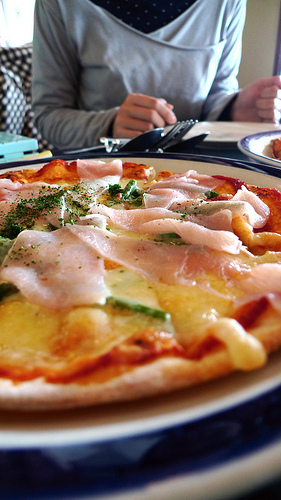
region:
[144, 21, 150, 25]
white dot on shirt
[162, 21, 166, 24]
white dot on shirt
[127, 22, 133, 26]
white dot on shirt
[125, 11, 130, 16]
white dot on shirt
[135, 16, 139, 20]
white dot on shirt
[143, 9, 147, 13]
white dot on shirt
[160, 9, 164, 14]
white dot on shirt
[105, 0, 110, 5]
white dot on shirt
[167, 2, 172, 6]
white dot on shirt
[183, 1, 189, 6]
white dot on shirt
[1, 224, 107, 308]
ham slices on the pizza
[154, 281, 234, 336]
pineapple chunks on the pizza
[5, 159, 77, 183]
brown toasted pizza crust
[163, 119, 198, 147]
a dinner fork on the table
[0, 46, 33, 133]
a black sofa with white polka dots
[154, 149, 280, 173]
a round pizza serving dish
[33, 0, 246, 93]
a grey long sleeve sweater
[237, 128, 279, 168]
a blue rim ceramic bowl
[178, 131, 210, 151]
a spoon on the table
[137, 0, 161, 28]
a black blouse with white polka dots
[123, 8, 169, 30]
edge of black shirt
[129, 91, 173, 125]
woman's fingers on table top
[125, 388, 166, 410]
shadow on the plate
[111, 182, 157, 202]
piece of green broccoli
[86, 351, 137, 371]
red sauce on pizza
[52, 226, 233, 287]
slices of pink ham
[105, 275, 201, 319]
melted white cheese on pie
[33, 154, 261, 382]
large pizza crust on plate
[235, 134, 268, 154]
deep dish blue and white dish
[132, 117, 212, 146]
silverware on table top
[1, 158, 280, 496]
a yummy looking pizza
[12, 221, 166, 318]
this appears to be chicken or turkey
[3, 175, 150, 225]
herbs are sprinkled on top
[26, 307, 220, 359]
the pizza is covered in cheese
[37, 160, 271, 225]
the crust is nicely browned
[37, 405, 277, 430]
the plate is white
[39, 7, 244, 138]
this girl is wearing a grey shirt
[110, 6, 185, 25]
she has on a black shirt under the grey one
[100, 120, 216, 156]
the girl has utensils in front of her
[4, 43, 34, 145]
black & white polka dots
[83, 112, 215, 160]
Two fork and spoons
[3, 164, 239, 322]
Green spice on pizza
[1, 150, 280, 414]
Light brown piece of crust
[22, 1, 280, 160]
Person sitting at the table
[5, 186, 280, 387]
Yellow cheese on pizza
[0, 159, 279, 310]
Pink piece of meat on pizza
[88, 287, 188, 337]
Green piece of topping on pizza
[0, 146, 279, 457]
Blue and white circle plate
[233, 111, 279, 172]
Blue and white plate in the distance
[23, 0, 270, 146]
Gray shirt on woman